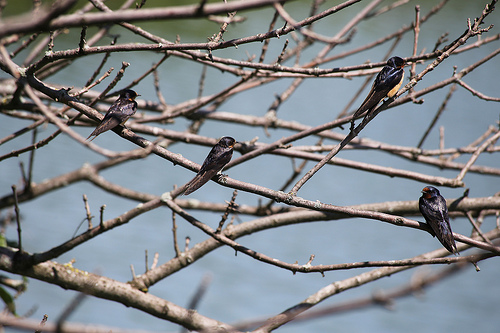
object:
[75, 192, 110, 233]
twigs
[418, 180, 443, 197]
bird head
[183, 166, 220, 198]
bird tail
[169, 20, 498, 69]
branches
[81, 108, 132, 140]
bird tail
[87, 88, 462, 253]
black birds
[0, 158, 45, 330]
green leaves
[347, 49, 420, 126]
bird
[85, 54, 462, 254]
four birds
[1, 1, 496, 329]
branches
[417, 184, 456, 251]
bird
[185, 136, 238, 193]
bird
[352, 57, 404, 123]
bird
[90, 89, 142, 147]
bird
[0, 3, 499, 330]
tree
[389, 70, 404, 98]
underbelly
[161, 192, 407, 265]
branch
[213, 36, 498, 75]
branch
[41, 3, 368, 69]
branch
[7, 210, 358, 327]
branch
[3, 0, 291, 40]
branch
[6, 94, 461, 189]
branch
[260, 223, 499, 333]
branch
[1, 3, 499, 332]
sky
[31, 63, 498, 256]
branch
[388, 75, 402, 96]
breast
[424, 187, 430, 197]
beaks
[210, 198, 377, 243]
branches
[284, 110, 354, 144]
branch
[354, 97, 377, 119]
tail